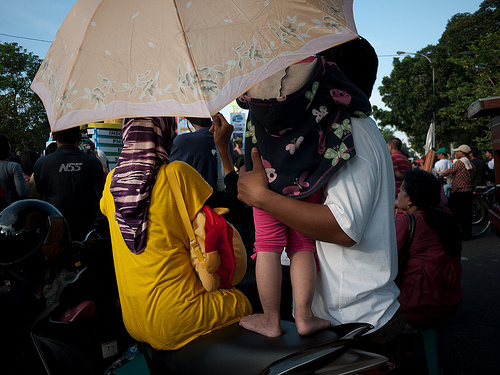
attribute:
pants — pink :
[250, 190, 325, 257]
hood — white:
[234, 71, 298, 103]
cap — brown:
[452, 141, 469, 152]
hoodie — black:
[236, 85, 363, 188]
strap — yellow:
[164, 171, 199, 256]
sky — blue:
[368, 17, 452, 53]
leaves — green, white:
[78, 25, 358, 115]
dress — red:
[396, 209, 453, 325]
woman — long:
[88, 126, 248, 330]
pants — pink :
[94, 98, 276, 358]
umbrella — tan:
[25, 0, 362, 134]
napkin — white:
[457, 155, 474, 172]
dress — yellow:
[96, 157, 254, 354]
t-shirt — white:
[307, 112, 403, 338]